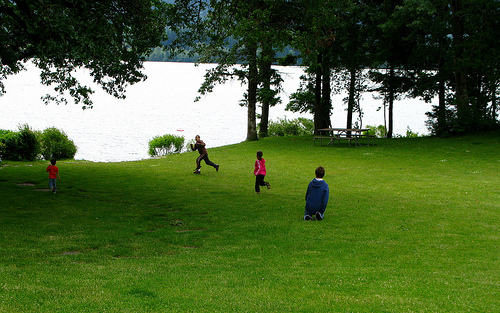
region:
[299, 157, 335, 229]
Boy leaning down in grass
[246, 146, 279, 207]
Girl running in grass field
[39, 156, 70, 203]
Little boy running in grass field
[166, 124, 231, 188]
Boy running to catch a frisbee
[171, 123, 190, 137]
Frisbee flying through the air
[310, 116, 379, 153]
Unused picnic table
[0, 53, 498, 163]
A body of water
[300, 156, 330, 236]
Boy in a blue sweater and jeans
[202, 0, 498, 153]
Trees on water line of lake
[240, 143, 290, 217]
Girl in pink jacket and black pants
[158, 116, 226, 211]
man trying to catch Frisbee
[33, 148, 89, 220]
child wearing red shirt running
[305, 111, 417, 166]
picnic table in park near trees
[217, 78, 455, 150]
trees with green leaves, water, and picnic table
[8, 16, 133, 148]
trees and plants near water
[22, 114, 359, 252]
four people playing at the park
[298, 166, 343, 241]
boy in blue sweatshirt sitting on grass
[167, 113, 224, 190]
man running to catch Frisbee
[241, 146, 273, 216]
child wearing pink running on grass in park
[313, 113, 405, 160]
empty picnic table in park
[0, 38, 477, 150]
a lake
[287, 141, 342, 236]
a child wearing a blue sweatshirt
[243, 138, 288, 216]
a child wearing a pink jacket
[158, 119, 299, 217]
children playing frisbee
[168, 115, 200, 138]
a frisbee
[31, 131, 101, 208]
a child wearing a red shirt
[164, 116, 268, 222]
a child going to catch a frisbee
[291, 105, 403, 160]
picnic tables near a lake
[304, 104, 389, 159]
picnic tables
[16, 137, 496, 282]
green grass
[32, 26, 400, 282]
lake and grassy field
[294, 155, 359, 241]
child wearing blue jacket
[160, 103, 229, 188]
child running to catch a frisbee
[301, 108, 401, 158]
brown picnic table on grass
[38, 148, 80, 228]
child running on grass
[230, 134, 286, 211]
child wearing a pink sweater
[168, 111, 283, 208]
two children playing frisbee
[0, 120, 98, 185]
two bushes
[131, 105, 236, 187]
child wearing all brown outfit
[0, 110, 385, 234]
four children playing on grass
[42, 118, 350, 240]
People are standing in the grass.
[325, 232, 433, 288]
Grass is green color.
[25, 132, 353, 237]
Four people are playing.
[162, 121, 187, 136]
Frisbee is white color.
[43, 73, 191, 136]
Water is seen behind the grass.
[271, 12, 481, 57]
Trees are green color.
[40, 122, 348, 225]
People are playing Frisbee.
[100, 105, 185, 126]
Water is blue color.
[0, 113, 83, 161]
Bushes are seen in the water border.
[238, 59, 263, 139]
Woods are brown color.